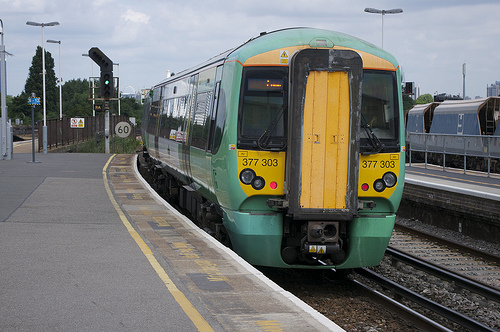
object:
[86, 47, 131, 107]
light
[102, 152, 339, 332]
line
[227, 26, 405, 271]
front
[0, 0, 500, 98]
blue sky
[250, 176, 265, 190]
lights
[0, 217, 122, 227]
crack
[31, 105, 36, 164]
pole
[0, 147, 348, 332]
sidewalk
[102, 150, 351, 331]
words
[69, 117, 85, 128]
sign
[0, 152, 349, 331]
platform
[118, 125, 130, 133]
number 60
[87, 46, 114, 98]
traffic light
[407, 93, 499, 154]
silver train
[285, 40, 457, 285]
train station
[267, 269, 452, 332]
pebbles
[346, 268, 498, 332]
tracks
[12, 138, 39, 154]
street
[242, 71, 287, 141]
window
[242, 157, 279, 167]
number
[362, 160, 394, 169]
numbers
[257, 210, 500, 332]
ground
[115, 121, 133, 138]
white sign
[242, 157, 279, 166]
black number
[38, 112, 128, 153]
fence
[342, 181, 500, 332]
track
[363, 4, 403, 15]
light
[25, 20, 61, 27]
light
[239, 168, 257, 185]
light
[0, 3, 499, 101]
clouds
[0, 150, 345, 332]
concrete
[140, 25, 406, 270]
train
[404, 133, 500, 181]
railing